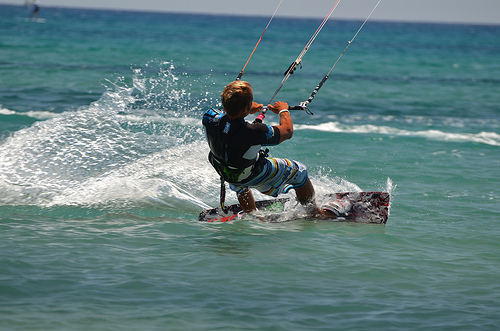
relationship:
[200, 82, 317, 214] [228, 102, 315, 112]
boarder touching bar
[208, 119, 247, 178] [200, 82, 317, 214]
best on boarder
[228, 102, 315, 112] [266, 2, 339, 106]
bar attached to rope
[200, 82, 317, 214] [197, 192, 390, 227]
boarder on board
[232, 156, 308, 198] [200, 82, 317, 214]
shorts are on boarder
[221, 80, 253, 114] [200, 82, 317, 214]
hair on boarder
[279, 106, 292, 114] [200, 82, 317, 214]
wristband on boarder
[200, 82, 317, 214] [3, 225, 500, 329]
boarder in ocean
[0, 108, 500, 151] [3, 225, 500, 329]
waves in ocean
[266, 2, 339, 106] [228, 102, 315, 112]
rope on bar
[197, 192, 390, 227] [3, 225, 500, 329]
board in ocean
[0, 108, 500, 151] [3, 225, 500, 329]
waves are in ocean